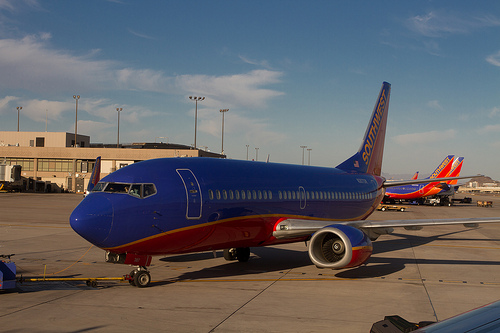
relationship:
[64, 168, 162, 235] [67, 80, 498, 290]
cockpit of plane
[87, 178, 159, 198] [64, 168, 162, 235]
windows of cockpit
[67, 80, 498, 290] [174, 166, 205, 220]
plane has door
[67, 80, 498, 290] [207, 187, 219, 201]
plane has window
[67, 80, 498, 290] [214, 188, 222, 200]
plane has window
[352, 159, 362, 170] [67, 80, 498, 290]
company logo on tail of plane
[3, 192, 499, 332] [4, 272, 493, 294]
runway has stripes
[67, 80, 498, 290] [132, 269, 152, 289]
plane has wheel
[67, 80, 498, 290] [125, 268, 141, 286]
plane has wheel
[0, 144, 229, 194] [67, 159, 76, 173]
building has window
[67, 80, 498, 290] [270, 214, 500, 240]
plane has wing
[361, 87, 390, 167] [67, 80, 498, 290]
writing on plane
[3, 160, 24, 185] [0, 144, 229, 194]
truck parked by building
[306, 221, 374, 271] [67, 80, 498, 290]
engine of plane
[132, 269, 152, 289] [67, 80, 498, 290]
wheel of plane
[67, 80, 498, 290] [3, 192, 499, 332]
plane on runway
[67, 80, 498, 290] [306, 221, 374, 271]
plane has engine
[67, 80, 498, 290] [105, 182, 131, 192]
plane has windshield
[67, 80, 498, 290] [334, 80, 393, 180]
plane has tail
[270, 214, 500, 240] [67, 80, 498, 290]
wing of plane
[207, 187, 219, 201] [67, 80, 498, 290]
window of plane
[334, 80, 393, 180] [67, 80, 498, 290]
tail of plane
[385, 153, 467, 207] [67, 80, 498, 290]
planes behind plane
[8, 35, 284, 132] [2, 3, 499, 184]
clouds in sky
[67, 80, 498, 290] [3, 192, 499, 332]
plane at runway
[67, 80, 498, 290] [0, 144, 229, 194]
plane near building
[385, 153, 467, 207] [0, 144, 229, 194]
planes near building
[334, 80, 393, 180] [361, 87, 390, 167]
tail says southwest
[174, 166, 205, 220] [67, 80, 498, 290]
door on plane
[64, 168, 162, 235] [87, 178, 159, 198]
cockpit has windows